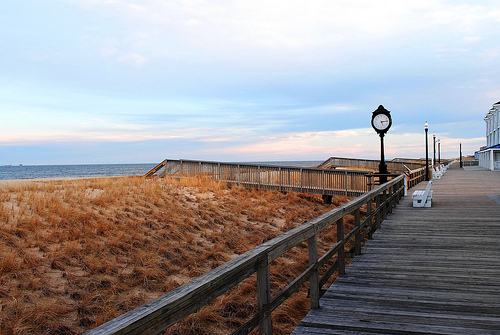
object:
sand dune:
[0, 173, 375, 335]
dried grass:
[90, 248, 164, 271]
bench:
[444, 164, 450, 169]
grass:
[115, 203, 242, 270]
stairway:
[142, 158, 182, 179]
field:
[0, 0, 500, 335]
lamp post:
[424, 128, 430, 181]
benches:
[448, 160, 457, 165]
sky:
[0, 0, 497, 166]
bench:
[435, 167, 444, 176]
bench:
[439, 165, 446, 174]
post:
[459, 143, 463, 168]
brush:
[40, 226, 71, 243]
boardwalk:
[287, 162, 499, 335]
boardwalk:
[326, 161, 423, 171]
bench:
[412, 180, 434, 208]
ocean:
[0, 161, 327, 180]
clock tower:
[371, 104, 393, 185]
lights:
[424, 121, 429, 129]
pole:
[438, 143, 440, 164]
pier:
[0, 100, 500, 335]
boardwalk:
[162, 175, 408, 198]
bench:
[433, 166, 443, 179]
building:
[477, 100, 500, 171]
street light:
[433, 131, 437, 137]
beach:
[0, 157, 476, 335]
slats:
[299, 308, 500, 334]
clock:
[372, 113, 389, 130]